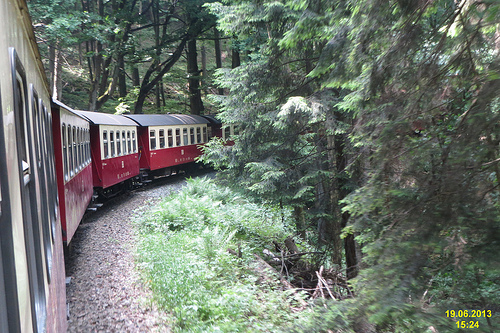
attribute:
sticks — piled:
[278, 237, 350, 321]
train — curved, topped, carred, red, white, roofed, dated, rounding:
[2, 2, 217, 311]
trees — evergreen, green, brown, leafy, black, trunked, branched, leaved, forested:
[201, 2, 496, 318]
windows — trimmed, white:
[101, 118, 215, 152]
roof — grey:
[66, 96, 205, 137]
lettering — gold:
[446, 307, 490, 331]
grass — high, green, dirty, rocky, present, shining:
[160, 172, 369, 332]